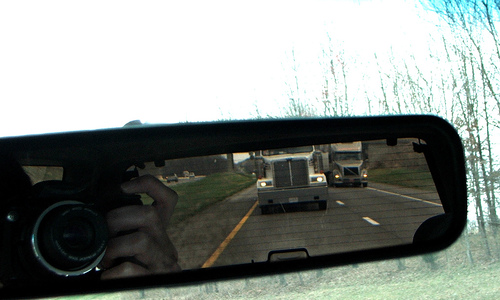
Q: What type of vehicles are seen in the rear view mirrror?
A: Tractor trailers.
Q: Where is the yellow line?
A: Side of the road.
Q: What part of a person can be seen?
A: Fingers.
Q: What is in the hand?
A: Camera.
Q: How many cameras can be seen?
A: 1.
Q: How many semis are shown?
A: 2.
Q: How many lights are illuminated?
A: 4.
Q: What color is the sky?
A: White.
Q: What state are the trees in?
A: Bare.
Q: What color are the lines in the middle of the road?
A: White.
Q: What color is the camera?
A: Black.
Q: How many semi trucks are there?
A: Two.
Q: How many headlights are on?
A: Four.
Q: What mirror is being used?
A: Rearview mirror.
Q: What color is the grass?
A: Green.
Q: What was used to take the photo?
A: Camera.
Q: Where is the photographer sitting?
A: Car.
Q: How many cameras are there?
A: One.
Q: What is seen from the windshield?
A: Trees.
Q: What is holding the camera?
A: Hand.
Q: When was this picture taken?
A: Daytime.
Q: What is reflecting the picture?
A: A mirror.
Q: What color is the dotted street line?
A: White.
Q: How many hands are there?
A: One.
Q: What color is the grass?
A: Green.